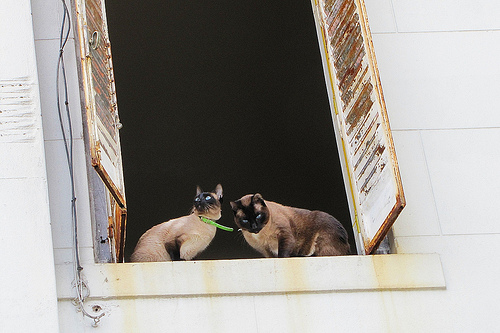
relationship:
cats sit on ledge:
[132, 183, 348, 257] [114, 264, 362, 289]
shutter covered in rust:
[331, 43, 373, 130] [326, 19, 356, 35]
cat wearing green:
[134, 179, 218, 259] [200, 218, 231, 229]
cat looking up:
[134, 179, 218, 259] [193, 183, 224, 215]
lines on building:
[72, 195, 83, 262] [393, 4, 499, 105]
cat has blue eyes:
[134, 179, 218, 259] [196, 196, 212, 202]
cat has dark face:
[134, 179, 218, 259] [236, 207, 266, 231]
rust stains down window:
[326, 19, 356, 35] [91, 0, 349, 257]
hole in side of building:
[18, 83, 23, 88] [393, 4, 499, 105]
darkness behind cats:
[131, 14, 285, 88] [132, 183, 348, 257]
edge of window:
[111, 254, 365, 268] [91, 0, 349, 257]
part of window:
[89, 129, 128, 259] [91, 0, 349, 257]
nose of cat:
[251, 223, 257, 230] [134, 179, 218, 259]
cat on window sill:
[134, 179, 218, 259] [114, 264, 362, 289]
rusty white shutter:
[333, 34, 359, 55] [331, 43, 373, 130]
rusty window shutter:
[333, 34, 359, 55] [331, 43, 373, 130]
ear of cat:
[214, 183, 223, 198] [134, 179, 218, 259]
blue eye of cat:
[207, 196, 212, 201] [134, 179, 218, 259]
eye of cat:
[257, 213, 262, 218] [134, 179, 218, 259]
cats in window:
[132, 183, 348, 257] [91, 0, 349, 257]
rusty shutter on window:
[333, 34, 359, 55] [91, 0, 349, 257]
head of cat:
[193, 183, 224, 215] [134, 179, 218, 259]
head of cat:
[229, 192, 270, 231] [134, 179, 218, 259]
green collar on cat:
[200, 218, 231, 229] [134, 179, 218, 259]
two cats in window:
[132, 183, 348, 257] [91, 0, 349, 257]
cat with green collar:
[134, 179, 218, 259] [200, 218, 231, 229]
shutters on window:
[335, 42, 375, 171] [91, 0, 349, 257]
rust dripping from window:
[326, 19, 356, 35] [91, 0, 349, 257]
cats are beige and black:
[132, 183, 348, 257] [246, 206, 256, 217]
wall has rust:
[102, 270, 138, 293] [326, 19, 356, 35]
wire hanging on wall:
[54, 68, 69, 110] [102, 270, 138, 293]